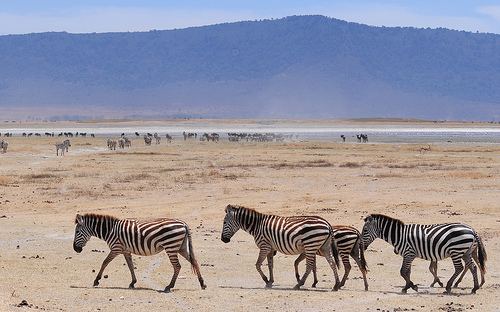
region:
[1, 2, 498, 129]
Distant mountains under a blue sky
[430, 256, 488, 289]
Legs of a baby zebra hidden by an adult zebra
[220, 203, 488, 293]
Two adult zebras with babies beside them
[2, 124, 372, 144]
Animals at the water's edge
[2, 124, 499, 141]
Distant body of water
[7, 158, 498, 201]
Scraggly tufts of brown grass in the dirt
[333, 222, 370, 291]
Hindquarters of a young zebra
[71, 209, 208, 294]
Single zebra in clear focus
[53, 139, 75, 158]
Lone out of focus animal walking toward the water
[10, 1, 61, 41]
white clouds in blue sky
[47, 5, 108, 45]
white clouds in blue sky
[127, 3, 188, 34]
white clouds in blue sky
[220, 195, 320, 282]
black and white striped zebra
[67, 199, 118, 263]
the head of a zebra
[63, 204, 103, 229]
the ear of a zebra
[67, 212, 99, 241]
the eye of a zebra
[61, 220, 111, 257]
the nose of a zebra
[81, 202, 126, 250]
the neck of a zebra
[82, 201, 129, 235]
the main of a zebra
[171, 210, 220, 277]
the tail of a zebra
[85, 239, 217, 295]
the legs of a zebra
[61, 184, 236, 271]
the body of a zebra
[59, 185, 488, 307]
three adult & one baby zebra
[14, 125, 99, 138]
other black animals at the water's edge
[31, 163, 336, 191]
some short weeds growing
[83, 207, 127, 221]
the zebra has a red/brown mane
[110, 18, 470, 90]
the mountain is covered with trees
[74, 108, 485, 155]
this appears to be the local watering hole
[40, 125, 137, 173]
zebras headed to the water hole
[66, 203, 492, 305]
beautiful zebras walking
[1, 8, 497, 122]
a mountain on the background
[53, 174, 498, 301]
zebras walking in a field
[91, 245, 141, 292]
front legs of zebra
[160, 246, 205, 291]
back legs of zebra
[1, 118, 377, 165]
animals on the background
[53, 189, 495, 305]
zebras walking to the left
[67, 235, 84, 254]
muzzle is color black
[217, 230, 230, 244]
muzzle is color black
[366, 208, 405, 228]
zebra is white and black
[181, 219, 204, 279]
tail of zebra is long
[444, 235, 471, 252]
black stripe on zebra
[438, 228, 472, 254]
black stripe on zebra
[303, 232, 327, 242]
black stripe on zebra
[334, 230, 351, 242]
black stripe on zebra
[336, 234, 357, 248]
black stripe on zebra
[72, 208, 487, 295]
four striped zebras walking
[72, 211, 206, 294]
zebra in front leads the other three zebras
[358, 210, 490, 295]
zebra walking in back of other three zebras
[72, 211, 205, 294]
zebra in front has black and white stripes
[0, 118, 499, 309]
animals on a desert plain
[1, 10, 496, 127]
mountains with trees on it near a desert plain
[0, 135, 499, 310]
desert plain is light brown and dry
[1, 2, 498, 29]
light blue and cloudy sky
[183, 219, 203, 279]
front zebra has furry tail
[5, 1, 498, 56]
The cloudy sky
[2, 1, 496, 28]
A cloudy sky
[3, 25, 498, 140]
A mountain range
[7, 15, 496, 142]
The mountain range